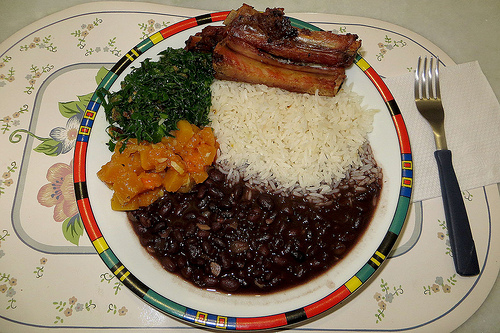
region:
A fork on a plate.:
[413, 56, 480, 276]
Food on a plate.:
[70, 2, 414, 332]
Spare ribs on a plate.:
[184, 3, 361, 98]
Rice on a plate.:
[206, 77, 381, 202]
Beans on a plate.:
[128, 143, 383, 295]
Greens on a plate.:
[97, 45, 217, 152]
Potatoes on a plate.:
[97, 120, 219, 212]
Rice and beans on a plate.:
[126, 78, 386, 295]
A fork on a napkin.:
[381, 54, 498, 276]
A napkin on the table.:
[380, 58, 499, 202]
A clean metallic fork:
[409, 52, 466, 125]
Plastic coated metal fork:
[433, 140, 490, 281]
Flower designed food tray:
[2, 95, 66, 272]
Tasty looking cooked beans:
[143, 213, 348, 270]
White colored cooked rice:
[219, 101, 327, 166]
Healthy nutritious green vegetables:
[118, 75, 207, 122]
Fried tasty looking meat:
[216, 1, 365, 94]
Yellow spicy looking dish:
[108, 143, 197, 192]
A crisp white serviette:
[463, 85, 493, 160]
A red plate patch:
[314, 305, 322, 313]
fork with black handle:
[401, 51, 470, 301]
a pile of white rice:
[214, 84, 359, 191]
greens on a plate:
[109, 52, 215, 141]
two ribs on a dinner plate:
[196, 0, 371, 92]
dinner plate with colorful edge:
[78, 71, 110, 291]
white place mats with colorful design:
[12, 14, 122, 88]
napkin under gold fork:
[451, 49, 488, 136]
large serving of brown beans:
[143, 172, 379, 292]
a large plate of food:
[63, 9, 408, 331]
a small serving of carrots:
[109, 116, 213, 225]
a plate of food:
[53, 15, 374, 328]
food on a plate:
[73, 16, 460, 306]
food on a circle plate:
[65, 8, 449, 332]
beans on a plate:
[97, 26, 450, 332]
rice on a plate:
[101, 18, 455, 316]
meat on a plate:
[79, 12, 407, 326]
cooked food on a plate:
[94, 12, 476, 329]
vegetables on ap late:
[103, 31, 265, 147]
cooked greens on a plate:
[65, 29, 277, 174]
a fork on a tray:
[339, 26, 498, 276]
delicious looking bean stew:
[165, 225, 292, 265]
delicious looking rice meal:
[211, 88, 362, 175]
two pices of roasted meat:
[217, 32, 348, 85]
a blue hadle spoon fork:
[411, 61, 496, 272]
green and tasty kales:
[131, 61, 211, 125]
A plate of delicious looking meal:
[80, 41, 390, 321]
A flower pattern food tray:
[16, 56, 68, 252]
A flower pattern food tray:
[388, 264, 459, 330]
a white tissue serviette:
[450, 63, 498, 144]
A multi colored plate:
[117, 45, 399, 324]